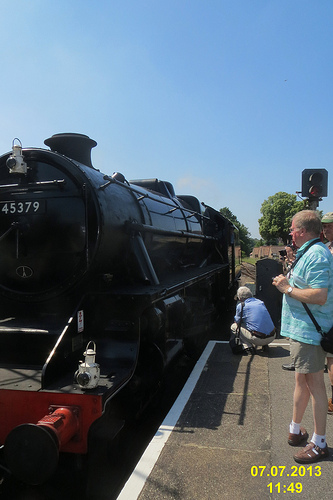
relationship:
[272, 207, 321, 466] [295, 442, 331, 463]
guy wearing sandals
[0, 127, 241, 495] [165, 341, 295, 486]
locomotive by a platform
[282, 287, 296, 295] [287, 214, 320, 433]
watch on man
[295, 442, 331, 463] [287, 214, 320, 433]
sandals on man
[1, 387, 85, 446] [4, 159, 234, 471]
paint on train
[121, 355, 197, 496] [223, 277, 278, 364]
line where man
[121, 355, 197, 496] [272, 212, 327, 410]
line where man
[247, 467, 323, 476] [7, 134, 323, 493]
date on photo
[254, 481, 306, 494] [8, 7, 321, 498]
time on photo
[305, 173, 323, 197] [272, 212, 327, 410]
light above man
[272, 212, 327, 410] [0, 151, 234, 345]
man looking train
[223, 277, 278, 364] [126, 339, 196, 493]
man near line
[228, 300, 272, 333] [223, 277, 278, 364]
shirt on man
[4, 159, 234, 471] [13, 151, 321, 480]
train leaving station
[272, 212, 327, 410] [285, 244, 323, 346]
man with bag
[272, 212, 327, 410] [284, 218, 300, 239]
man with glasses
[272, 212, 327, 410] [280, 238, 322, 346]
man with shirt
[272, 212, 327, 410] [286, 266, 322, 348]
man with bag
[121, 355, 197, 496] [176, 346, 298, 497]
line on platform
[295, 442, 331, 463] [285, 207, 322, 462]
sandals on man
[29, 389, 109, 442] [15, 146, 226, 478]
bumper on train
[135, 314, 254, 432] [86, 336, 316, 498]
shadow on asphalt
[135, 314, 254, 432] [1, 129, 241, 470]
shadow of train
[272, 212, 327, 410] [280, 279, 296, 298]
man wearing watch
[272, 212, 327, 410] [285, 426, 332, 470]
man wearing sandals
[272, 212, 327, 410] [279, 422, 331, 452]
man wearing socks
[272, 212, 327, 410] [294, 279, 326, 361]
man carrying bag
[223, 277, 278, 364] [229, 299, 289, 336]
man has shirt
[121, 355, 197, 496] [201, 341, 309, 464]
line on pavement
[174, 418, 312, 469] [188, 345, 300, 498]
line on pavement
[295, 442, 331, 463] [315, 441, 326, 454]
sandals with buckle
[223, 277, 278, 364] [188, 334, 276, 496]
man on pavement